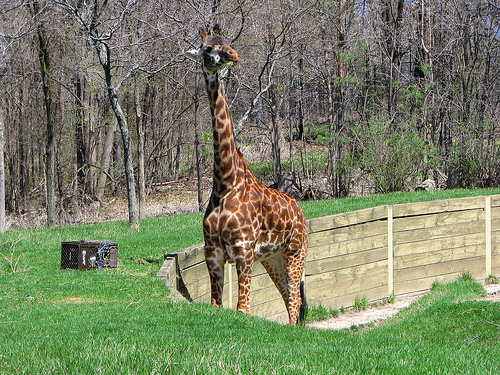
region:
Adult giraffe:
[182, 23, 324, 328]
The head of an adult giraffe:
[181, 21, 245, 72]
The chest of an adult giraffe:
[197, 180, 257, 265]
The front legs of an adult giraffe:
[202, 240, 256, 315]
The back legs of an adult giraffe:
[262, 247, 312, 331]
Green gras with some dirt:
[6, 282, 163, 373]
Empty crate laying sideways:
[58, 234, 130, 273]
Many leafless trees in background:
[3, 1, 176, 226]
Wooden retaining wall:
[315, 190, 498, 315]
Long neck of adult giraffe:
[200, 66, 247, 192]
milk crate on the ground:
[57, 238, 120, 271]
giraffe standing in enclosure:
[196, 20, 311, 326]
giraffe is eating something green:
[192, 24, 236, 71]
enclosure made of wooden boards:
[163, 192, 495, 329]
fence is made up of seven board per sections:
[391, 193, 489, 297]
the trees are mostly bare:
[9, 1, 496, 219]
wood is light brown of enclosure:
[390, 195, 485, 265]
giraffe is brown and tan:
[185, 20, 310, 321]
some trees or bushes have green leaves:
[315, 70, 437, 187]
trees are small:
[0, 0, 497, 220]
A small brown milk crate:
[58, 237, 120, 274]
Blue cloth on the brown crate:
[92, 246, 116, 271]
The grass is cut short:
[120, 302, 214, 374]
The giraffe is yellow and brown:
[175, 20, 321, 322]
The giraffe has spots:
[228, 202, 286, 237]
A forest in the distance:
[0, 31, 136, 207]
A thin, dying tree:
[72, 12, 150, 229]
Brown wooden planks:
[396, 205, 481, 279]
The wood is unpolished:
[329, 220, 417, 302]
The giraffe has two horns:
[195, 19, 227, 46]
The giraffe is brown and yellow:
[185, 29, 315, 319]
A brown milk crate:
[62, 233, 120, 274]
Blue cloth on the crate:
[96, 243, 110, 271]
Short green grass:
[50, 307, 150, 368]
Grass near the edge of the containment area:
[138, 265, 165, 311]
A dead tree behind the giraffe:
[89, 23, 152, 213]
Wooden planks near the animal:
[392, 212, 480, 284]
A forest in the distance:
[0, 5, 470, 145]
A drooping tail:
[295, 255, 327, 312]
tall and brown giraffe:
[183, 48, 377, 353]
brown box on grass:
[63, 218, 98, 265]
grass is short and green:
[32, 259, 159, 362]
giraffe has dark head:
[196, 13, 242, 64]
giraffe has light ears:
[188, 36, 204, 60]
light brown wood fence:
[330, 213, 412, 293]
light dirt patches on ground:
[335, 283, 438, 332]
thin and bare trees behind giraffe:
[84, 36, 257, 209]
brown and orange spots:
[178, 96, 325, 251]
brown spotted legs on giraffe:
[272, 247, 317, 329]